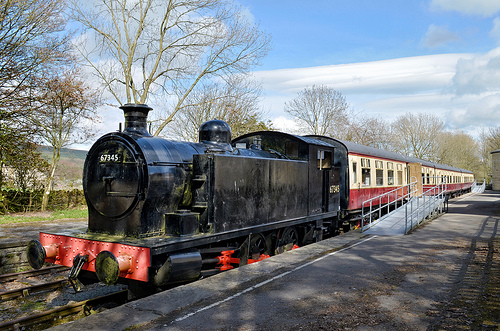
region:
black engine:
[79, 113, 247, 274]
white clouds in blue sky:
[260, 39, 280, 79]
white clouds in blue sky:
[349, 42, 391, 79]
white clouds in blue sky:
[296, 23, 367, 83]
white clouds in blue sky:
[410, 35, 438, 63]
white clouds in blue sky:
[269, 19, 317, 57]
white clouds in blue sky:
[330, 0, 384, 61]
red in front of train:
[14, 238, 153, 278]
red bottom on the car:
[352, 186, 424, 204]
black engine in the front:
[94, 151, 336, 243]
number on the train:
[83, 148, 125, 175]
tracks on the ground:
[430, 203, 499, 329]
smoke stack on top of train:
[121, 106, 152, 135]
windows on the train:
[363, 173, 417, 192]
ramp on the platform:
[368, 187, 448, 239]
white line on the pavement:
[145, 271, 361, 316]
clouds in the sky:
[310, 60, 452, 91]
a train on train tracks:
[35, 104, 477, 299]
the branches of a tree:
[93, 5, 206, 97]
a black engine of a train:
[28, 96, 342, 287]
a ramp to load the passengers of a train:
[357, 179, 447, 241]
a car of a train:
[348, 146, 408, 211]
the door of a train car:
[348, 153, 363, 210]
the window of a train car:
[358, 156, 373, 187]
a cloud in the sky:
[280, 44, 453, 92]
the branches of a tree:
[290, 85, 345, 130]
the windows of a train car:
[358, 157, 405, 189]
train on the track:
[45, 96, 485, 274]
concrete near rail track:
[282, 259, 424, 315]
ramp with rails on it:
[369, 176, 448, 231]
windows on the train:
[353, 162, 400, 183]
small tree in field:
[42, 75, 74, 201]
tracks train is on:
[21, 271, 76, 314]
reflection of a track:
[466, 207, 495, 328]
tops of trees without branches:
[286, 82, 436, 150]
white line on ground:
[200, 295, 232, 310]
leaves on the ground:
[333, 299, 389, 324]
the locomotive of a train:
[26, 96, 349, 248]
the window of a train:
[360, 155, 372, 191]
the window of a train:
[375, 160, 384, 183]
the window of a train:
[388, 160, 395, 182]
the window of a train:
[396, 161, 402, 181]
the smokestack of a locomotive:
[118, 98, 151, 134]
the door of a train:
[348, 150, 360, 209]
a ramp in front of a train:
[354, 176, 449, 236]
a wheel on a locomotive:
[243, 236, 273, 263]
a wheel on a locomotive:
[278, 228, 298, 251]